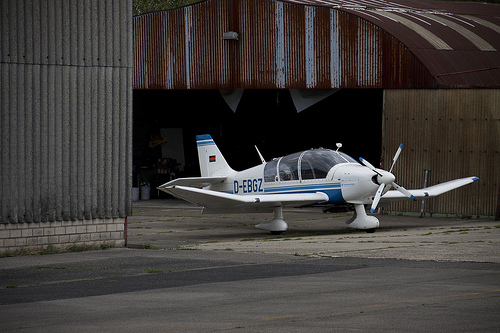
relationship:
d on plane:
[231, 177, 244, 194] [156, 126, 488, 224]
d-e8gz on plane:
[228, 170, 266, 198] [156, 126, 488, 224]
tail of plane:
[194, 130, 230, 177] [156, 126, 488, 224]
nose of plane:
[381, 167, 397, 187] [156, 126, 488, 224]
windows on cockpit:
[261, 148, 353, 181] [261, 145, 383, 193]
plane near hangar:
[156, 126, 488, 224] [2, 4, 499, 232]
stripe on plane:
[257, 180, 348, 198] [156, 126, 488, 224]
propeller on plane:
[366, 143, 415, 208] [156, 126, 488, 224]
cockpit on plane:
[261, 145, 383, 193] [156, 126, 488, 224]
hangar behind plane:
[2, 4, 499, 232] [156, 126, 488, 224]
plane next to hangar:
[156, 126, 488, 224] [2, 4, 499, 232]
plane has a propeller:
[156, 126, 488, 224] [366, 143, 415, 208]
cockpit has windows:
[261, 145, 383, 193] [261, 148, 353, 181]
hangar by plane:
[2, 4, 499, 232] [156, 126, 488, 224]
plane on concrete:
[156, 126, 488, 224] [2, 193, 492, 333]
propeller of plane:
[366, 143, 415, 208] [156, 126, 488, 224]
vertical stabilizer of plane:
[161, 173, 228, 191] [156, 126, 488, 224]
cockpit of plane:
[261, 145, 383, 193] [156, 126, 488, 224]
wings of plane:
[166, 164, 484, 209] [156, 126, 488, 224]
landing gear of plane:
[247, 205, 381, 241] [156, 126, 488, 224]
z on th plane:
[259, 177, 265, 193] [156, 126, 488, 224]